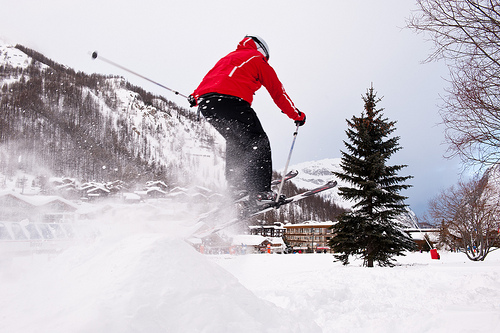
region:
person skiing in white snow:
[175, 31, 330, 263]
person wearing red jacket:
[199, 38, 297, 127]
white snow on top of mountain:
[33, 228, 113, 281]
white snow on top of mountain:
[33, 285, 104, 323]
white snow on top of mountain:
[169, 265, 213, 294]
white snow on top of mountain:
[160, 298, 231, 330]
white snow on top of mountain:
[247, 259, 305, 307]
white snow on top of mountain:
[327, 274, 376, 322]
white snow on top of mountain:
[404, 269, 454, 310]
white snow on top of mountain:
[364, 300, 444, 329]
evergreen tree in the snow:
[322, 88, 422, 275]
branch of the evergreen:
[390, 240, 411, 249]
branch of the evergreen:
[335, 243, 357, 258]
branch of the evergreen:
[339, 186, 356, 199]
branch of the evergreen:
[332, 170, 362, 185]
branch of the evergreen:
[392, 180, 409, 195]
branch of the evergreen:
[385, 145, 400, 160]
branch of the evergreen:
[382, 150, 394, 162]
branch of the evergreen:
[336, 160, 356, 177]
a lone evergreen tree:
[332, 83, 416, 270]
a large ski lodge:
[275, 216, 465, 253]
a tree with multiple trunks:
[431, 180, 498, 264]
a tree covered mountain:
[3, 33, 183, 202]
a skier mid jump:
[86, 31, 341, 260]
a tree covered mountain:
[283, 154, 427, 235]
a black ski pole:
[92, 53, 194, 103]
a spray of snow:
[13, 101, 275, 299]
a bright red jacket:
[185, 34, 314, 121]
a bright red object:
[426, 245, 441, 262]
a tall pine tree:
[328, 81, 411, 270]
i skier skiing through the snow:
[82, 30, 341, 238]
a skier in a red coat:
[81, 30, 342, 262]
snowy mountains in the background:
[1, 30, 499, 251]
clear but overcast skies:
[0, 0, 499, 225]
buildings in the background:
[0, 190, 499, 255]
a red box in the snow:
[426, 243, 442, 262]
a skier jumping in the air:
[87, 31, 339, 250]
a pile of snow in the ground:
[25, 229, 297, 329]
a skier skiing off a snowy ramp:
[6, 30, 346, 331]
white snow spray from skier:
[47, 148, 249, 298]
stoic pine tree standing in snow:
[333, 90, 409, 281]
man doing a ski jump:
[163, 34, 332, 237]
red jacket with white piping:
[173, 33, 310, 127]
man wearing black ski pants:
[198, 95, 284, 210]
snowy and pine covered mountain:
[5, 33, 198, 233]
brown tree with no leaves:
[435, 179, 497, 266]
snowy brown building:
[277, 215, 338, 262]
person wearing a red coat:
[426, 244, 441, 260]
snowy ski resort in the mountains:
[22, 21, 469, 301]